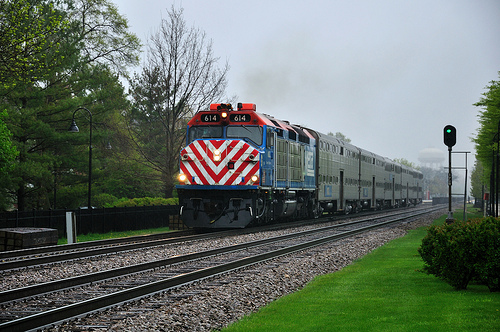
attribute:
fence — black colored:
[4, 201, 176, 236]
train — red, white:
[169, 99, 431, 234]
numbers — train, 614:
[190, 100, 268, 128]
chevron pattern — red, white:
[175, 136, 265, 184]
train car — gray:
[312, 135, 361, 210]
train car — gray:
[355, 143, 386, 202]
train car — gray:
[383, 157, 405, 201]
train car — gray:
[410, 167, 425, 200]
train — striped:
[192, 110, 426, 210]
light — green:
[446, 126, 453, 136]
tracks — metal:
[2, 216, 344, 331]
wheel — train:
[310, 204, 324, 219]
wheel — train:
[329, 200, 344, 212]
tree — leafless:
[141, 26, 259, 106]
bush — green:
[409, 212, 499, 298]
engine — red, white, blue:
[135, 97, 325, 232]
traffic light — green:
[439, 127, 465, 147]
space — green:
[245, 222, 495, 324]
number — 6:
[229, 110, 239, 120]